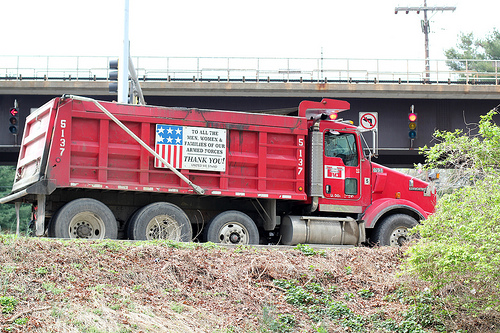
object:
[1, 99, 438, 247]
truck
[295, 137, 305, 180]
numbers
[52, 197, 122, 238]
tire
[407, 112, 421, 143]
signal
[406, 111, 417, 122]
light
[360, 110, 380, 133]
sign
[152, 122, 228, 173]
sign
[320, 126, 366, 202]
door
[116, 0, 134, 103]
pole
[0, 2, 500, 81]
sky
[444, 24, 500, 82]
tree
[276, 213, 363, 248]
tank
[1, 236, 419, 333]
grass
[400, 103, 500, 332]
shrub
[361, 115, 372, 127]
black arrow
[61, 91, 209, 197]
bar